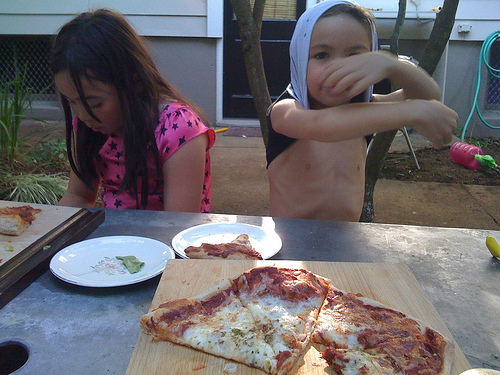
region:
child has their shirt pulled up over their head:
[251, 2, 423, 167]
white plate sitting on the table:
[54, 236, 169, 294]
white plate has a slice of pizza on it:
[187, 212, 299, 267]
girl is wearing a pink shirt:
[67, 118, 208, 216]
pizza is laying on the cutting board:
[147, 283, 454, 368]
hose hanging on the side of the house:
[465, 37, 495, 126]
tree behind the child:
[226, 9, 285, 109]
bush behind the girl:
[3, 83, 70, 201]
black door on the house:
[222, 0, 293, 132]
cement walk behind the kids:
[392, 183, 488, 220]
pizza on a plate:
[186, 234, 263, 264]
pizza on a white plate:
[180, 230, 265, 262]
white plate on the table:
[48, 230, 175, 294]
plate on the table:
[50, 226, 177, 283]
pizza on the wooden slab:
[146, 263, 461, 373]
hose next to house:
[460, 33, 499, 149]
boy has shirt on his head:
[280, 0, 402, 109]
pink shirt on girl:
[56, 130, 213, 207]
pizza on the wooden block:
[1, 203, 47, 238]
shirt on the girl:
[51, 134, 223, 212]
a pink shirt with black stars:
[70, 108, 217, 219]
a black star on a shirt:
[112, 196, 121, 206]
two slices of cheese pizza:
[141, 266, 333, 373]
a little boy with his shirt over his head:
[255, 2, 453, 228]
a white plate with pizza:
[172, 221, 283, 262]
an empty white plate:
[47, 235, 174, 288]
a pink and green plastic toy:
[448, 135, 498, 167]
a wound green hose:
[457, 22, 497, 144]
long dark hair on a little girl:
[37, 8, 215, 217]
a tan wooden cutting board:
[123, 251, 473, 373]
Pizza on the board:
[141, 268, 456, 373]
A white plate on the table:
[48, 235, 170, 290]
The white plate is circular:
[49, 234, 174, 286]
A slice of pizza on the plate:
[184, 233, 259, 258]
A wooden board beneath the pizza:
[123, 259, 475, 374]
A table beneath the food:
[4, 205, 498, 372]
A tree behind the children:
[230, 0, 456, 220]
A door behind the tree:
[222, 1, 306, 119]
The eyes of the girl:
[65, 95, 104, 106]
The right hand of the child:
[411, 97, 457, 144]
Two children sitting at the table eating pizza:
[33, 3, 481, 373]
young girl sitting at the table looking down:
[35, 6, 232, 207]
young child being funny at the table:
[260, 0, 475, 222]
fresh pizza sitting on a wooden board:
[137, 254, 469, 367]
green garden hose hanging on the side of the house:
[460, 34, 499, 151]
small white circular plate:
[45, 236, 170, 286]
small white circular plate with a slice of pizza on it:
[172, 216, 289, 261]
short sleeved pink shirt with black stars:
[58, 102, 230, 216]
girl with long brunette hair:
[30, 12, 199, 201]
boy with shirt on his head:
[285, 3, 402, 110]